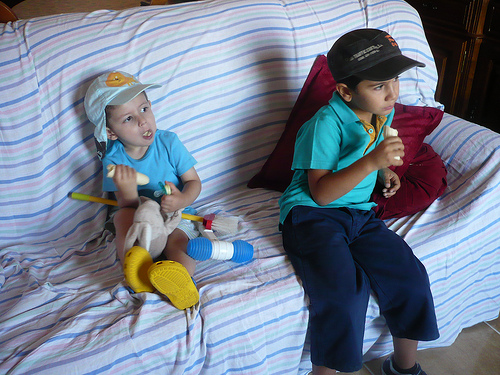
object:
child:
[82, 67, 202, 313]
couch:
[3, 3, 499, 374]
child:
[277, 26, 440, 372]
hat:
[81, 68, 164, 163]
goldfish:
[107, 70, 138, 90]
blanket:
[2, 6, 499, 375]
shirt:
[274, 84, 397, 230]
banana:
[382, 123, 403, 166]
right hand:
[377, 137, 406, 169]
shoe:
[147, 261, 201, 310]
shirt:
[100, 128, 200, 218]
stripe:
[374, 19, 421, 30]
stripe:
[366, 3, 414, 11]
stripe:
[401, 42, 430, 52]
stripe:
[463, 135, 499, 167]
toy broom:
[70, 193, 240, 236]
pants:
[281, 199, 439, 373]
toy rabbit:
[123, 199, 182, 262]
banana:
[105, 163, 151, 187]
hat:
[324, 25, 426, 93]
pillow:
[243, 53, 443, 200]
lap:
[103, 198, 204, 247]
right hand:
[113, 162, 142, 189]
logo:
[383, 32, 398, 50]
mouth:
[139, 127, 154, 143]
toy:
[185, 208, 256, 264]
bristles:
[212, 213, 240, 237]